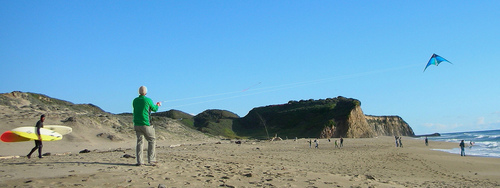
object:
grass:
[146, 96, 363, 141]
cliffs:
[0, 90, 415, 144]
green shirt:
[134, 96, 161, 127]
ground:
[0, 135, 500, 188]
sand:
[1, 135, 500, 188]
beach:
[0, 135, 499, 187]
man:
[27, 115, 47, 159]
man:
[459, 140, 466, 157]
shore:
[0, 135, 500, 188]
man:
[125, 78, 172, 173]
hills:
[0, 91, 414, 155]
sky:
[0, 0, 500, 134]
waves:
[417, 129, 500, 157]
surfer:
[29, 112, 47, 157]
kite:
[423, 53, 453, 73]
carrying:
[0, 124, 72, 142]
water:
[412, 130, 499, 156]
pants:
[134, 125, 157, 167]